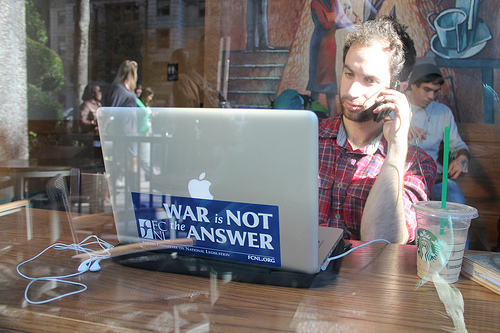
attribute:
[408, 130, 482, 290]
cup — used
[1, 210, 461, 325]
table — wooden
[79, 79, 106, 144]
woman — blonde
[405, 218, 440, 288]
logo — Starbucks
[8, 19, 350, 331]
reflection — people in window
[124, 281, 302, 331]
wood — dark brown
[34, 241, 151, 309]
headphones — white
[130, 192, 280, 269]
sticker — blue, anti-war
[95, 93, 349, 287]
laptop — cover, Apple, silver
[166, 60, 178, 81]
sign — restroom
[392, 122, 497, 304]
cup — plastic, Starbucks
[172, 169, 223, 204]
logo — apple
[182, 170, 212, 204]
logo — white, apple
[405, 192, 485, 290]
cup — starbucks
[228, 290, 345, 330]
grain — dark brown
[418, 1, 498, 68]
cup painting — plate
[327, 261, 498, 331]
wood grain — dark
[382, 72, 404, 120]
phone — black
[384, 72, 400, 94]
ear — man's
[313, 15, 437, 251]
man — beaded, balding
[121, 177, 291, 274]
sticker — blue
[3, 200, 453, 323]
top — table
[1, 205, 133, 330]
earbuds — pair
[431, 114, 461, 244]
straw — green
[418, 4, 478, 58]
cup — coffee